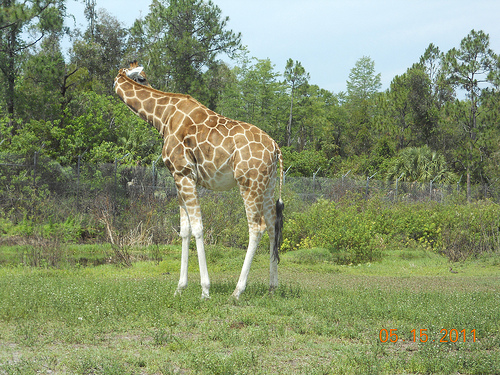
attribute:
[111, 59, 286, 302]
giraffe — tall, brown, white, spotted, looking backward, tan, contained, standing alone, standing on ground, looking to side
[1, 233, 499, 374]
grass — green, short, brown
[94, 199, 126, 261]
sticks — brown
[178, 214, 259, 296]
giraffe's legs — white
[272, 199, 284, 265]
hair — black, long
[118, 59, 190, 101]
hair — brown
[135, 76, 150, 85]
eyelashes — black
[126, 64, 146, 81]
ear — white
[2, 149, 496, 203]
fencing — tall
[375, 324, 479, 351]
date stamp — orange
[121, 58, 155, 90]
giraffe's head — turned around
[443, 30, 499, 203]
tree — tall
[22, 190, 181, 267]
bushes — brown